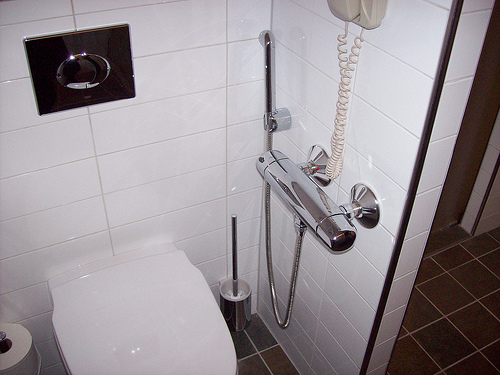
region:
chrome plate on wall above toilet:
[23, 20, 138, 115]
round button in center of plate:
[56, 50, 110, 90]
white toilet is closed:
[43, 235, 238, 372]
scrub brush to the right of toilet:
[218, 215, 255, 332]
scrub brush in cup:
[219, 280, 252, 332]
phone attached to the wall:
[325, 0, 381, 180]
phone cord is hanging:
[325, 21, 365, 179]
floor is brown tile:
[232, 316, 304, 373]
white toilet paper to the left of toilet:
[1, 322, 37, 374]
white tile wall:
[1, 1, 261, 373]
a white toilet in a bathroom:
[48, 242, 241, 374]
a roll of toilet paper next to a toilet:
[0, 319, 45, 372]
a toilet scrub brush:
[218, 213, 258, 303]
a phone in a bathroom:
[325, 1, 388, 30]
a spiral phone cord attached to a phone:
[317, 20, 365, 181]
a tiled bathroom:
[0, 0, 499, 373]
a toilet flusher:
[22, 18, 136, 119]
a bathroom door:
[426, 0, 499, 237]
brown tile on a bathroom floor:
[232, 225, 499, 374]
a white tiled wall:
[1, 0, 271, 374]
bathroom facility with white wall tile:
[0, 0, 496, 373]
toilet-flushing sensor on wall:
[20, 20, 135, 116]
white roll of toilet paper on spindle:
[0, 317, 40, 372]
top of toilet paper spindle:
[0, 326, 5, 346]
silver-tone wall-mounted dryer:
[251, 31, 378, 331]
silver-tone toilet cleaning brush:
[216, 213, 253, 335]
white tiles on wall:
[0, 49, 499, 374]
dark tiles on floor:
[228, 225, 499, 372]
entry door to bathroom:
[426, 0, 499, 249]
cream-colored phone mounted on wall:
[326, 0, 389, 182]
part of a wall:
[409, 198, 419, 219]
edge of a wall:
[389, 241, 396, 256]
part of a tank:
[158, 300, 168, 330]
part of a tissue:
[21, 345, 33, 357]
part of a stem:
[233, 229, 241, 236]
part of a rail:
[311, 210, 318, 255]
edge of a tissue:
[89, 124, 107, 140]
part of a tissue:
[12, 331, 39, 346]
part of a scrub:
[233, 248, 246, 303]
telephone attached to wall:
[311, 0, 396, 188]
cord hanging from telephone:
[312, 18, 362, 183]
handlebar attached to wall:
[248, 135, 381, 259]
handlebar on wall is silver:
[246, 134, 389, 261]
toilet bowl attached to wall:
[23, 245, 243, 373]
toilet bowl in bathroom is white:
[33, 243, 238, 373]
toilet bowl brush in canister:
[208, 210, 258, 335]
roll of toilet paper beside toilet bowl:
[0, 318, 47, 374]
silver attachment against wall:
[8, 18, 135, 120]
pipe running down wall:
[250, 25, 310, 330]